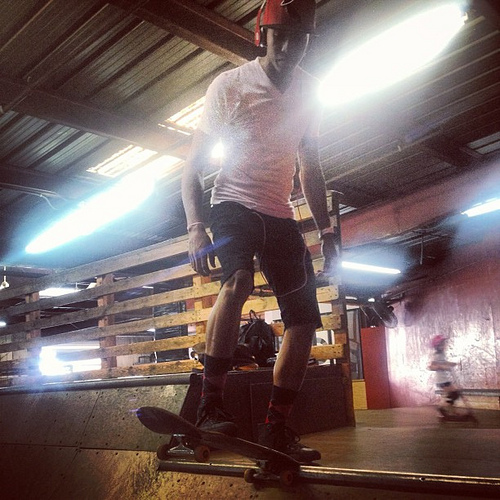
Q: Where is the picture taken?
A: A skatepark.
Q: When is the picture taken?
A: Daytime.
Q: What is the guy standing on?
A: A skateboard.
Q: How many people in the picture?
A: Two.